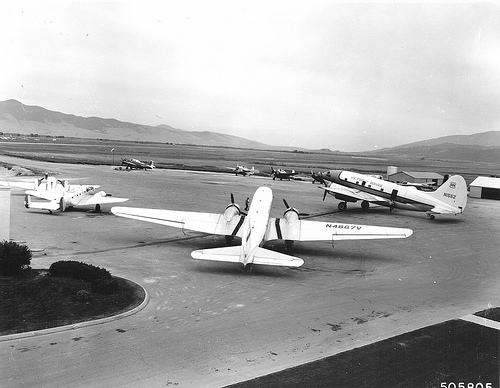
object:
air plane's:
[0, 172, 129, 215]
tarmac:
[5, 334, 92, 384]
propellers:
[317, 180, 332, 202]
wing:
[317, 187, 387, 203]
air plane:
[110, 186, 415, 275]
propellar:
[282, 197, 310, 220]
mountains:
[144, 124, 188, 139]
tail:
[191, 246, 305, 268]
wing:
[312, 183, 391, 206]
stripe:
[334, 179, 421, 205]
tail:
[426, 174, 468, 215]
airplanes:
[309, 170, 324, 184]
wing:
[110, 205, 245, 239]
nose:
[316, 170, 328, 179]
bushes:
[47, 260, 109, 279]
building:
[0, 181, 11, 244]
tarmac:
[327, 247, 474, 297]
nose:
[269, 166, 275, 176]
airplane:
[114, 157, 155, 173]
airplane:
[263, 167, 299, 182]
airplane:
[225, 162, 259, 178]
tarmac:
[75, 162, 302, 186]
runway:
[1, 155, 498, 387]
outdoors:
[0, 2, 499, 384]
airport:
[2, 140, 496, 387]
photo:
[0, 0, 499, 387]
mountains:
[379, 130, 499, 161]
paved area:
[2, 169, 498, 386]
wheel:
[360, 201, 369, 211]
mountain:
[2, 97, 76, 122]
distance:
[8, 0, 498, 226]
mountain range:
[2, 98, 264, 148]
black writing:
[325, 224, 361, 231]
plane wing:
[265, 218, 414, 243]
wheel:
[338, 202, 348, 211]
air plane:
[306, 168, 468, 220]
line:
[459, 314, 499, 331]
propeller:
[223, 192, 247, 216]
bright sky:
[3, 0, 497, 126]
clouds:
[166, 17, 374, 92]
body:
[242, 186, 273, 245]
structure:
[387, 170, 444, 187]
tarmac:
[141, 311, 249, 386]